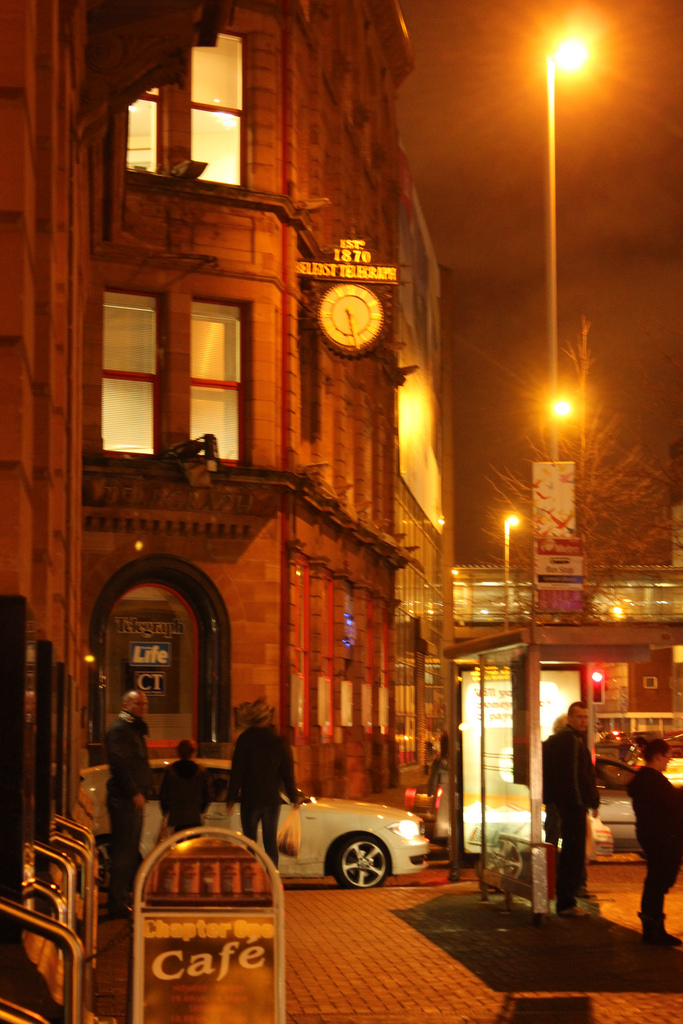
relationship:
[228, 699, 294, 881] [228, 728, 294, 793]
man in a jacket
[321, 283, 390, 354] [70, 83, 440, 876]
clock on building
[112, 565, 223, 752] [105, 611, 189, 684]
window with advertising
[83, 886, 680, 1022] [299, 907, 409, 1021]
pavers on walkway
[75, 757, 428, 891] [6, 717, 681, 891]
cars on street